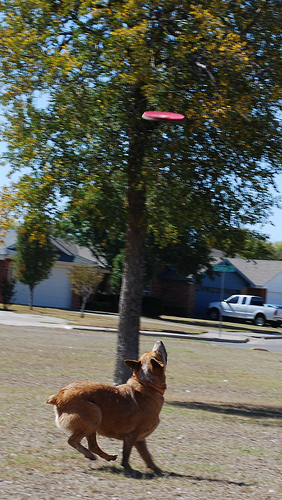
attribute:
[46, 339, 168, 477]
dog — looking, reddish brown, brown, playing, red, watching, standing, stopping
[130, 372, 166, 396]
collar — orange, red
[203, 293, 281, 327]
truck — white, parked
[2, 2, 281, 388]
tree — brown, tall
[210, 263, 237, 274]
street sign — green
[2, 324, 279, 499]
field — grassy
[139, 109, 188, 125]
frisbee — red, in the air, pink, white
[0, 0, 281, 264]
leaves — yellow, green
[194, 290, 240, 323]
door — blue, garage door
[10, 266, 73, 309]
door — garage door, white